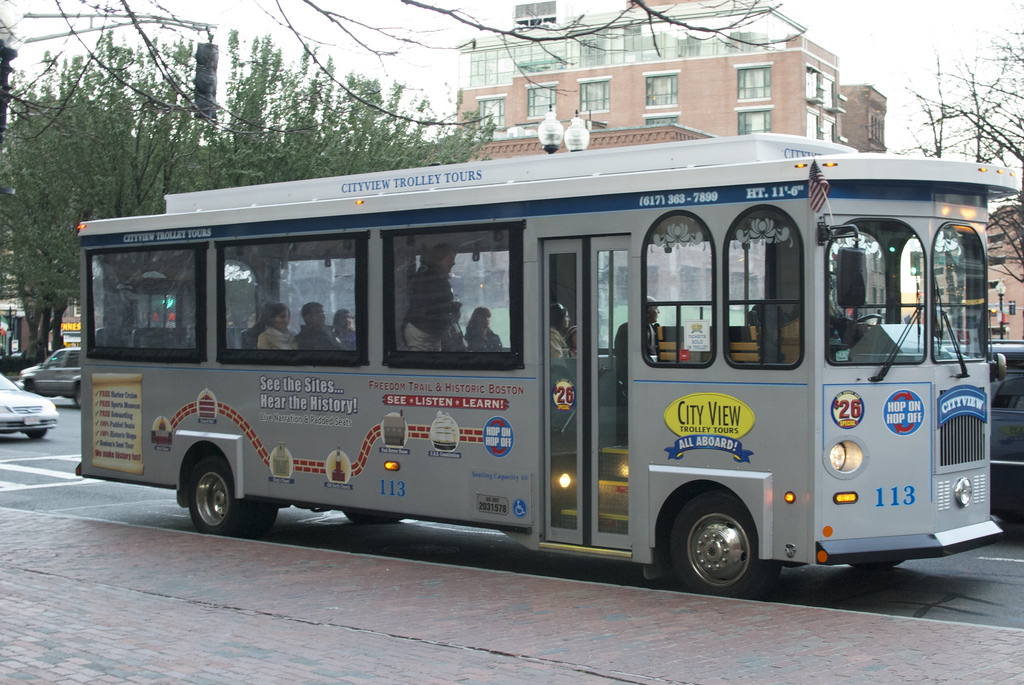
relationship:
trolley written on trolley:
[370, 155, 440, 210] [212, 211, 802, 532]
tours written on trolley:
[426, 155, 493, 207] [212, 211, 802, 532]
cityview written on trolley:
[333, 174, 392, 214] [212, 211, 802, 532]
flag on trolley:
[776, 162, 854, 236] [107, 162, 854, 529]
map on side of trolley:
[144, 369, 429, 484] [67, 233, 913, 484]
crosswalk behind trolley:
[19, 421, 152, 532] [19, 162, 1021, 532]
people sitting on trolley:
[247, 294, 362, 370] [52, 125, 994, 598]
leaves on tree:
[39, 50, 60, 69] [8, 16, 471, 296]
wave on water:
[371, 473, 419, 499] [637, 432, 735, 461]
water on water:
[663, 434, 753, 464] [667, 430, 751, 468]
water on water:
[663, 434, 753, 464] [661, 429, 759, 465]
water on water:
[663, 434, 753, 464] [655, 433, 754, 463]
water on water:
[663, 434, 753, 464] [661, 433, 756, 460]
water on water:
[663, 434, 753, 464] [662, 426, 755, 464]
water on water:
[663, 434, 753, 464] [642, 426, 753, 468]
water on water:
[663, 434, 753, 464] [652, 417, 752, 455]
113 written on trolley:
[862, 448, 954, 543] [113, 170, 954, 543]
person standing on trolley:
[392, 260, 514, 359] [144, 215, 980, 513]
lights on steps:
[550, 438, 636, 503] [551, 430, 635, 536]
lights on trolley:
[550, 438, 636, 503] [52, 125, 994, 598]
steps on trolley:
[551, 430, 635, 536] [52, 125, 994, 598]